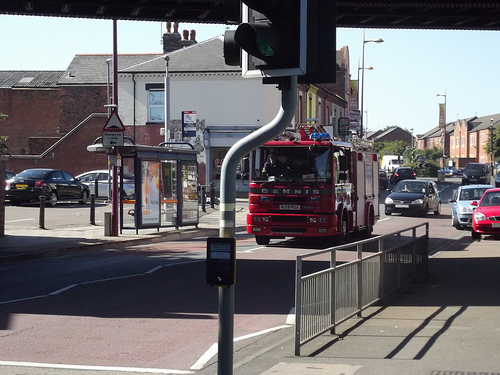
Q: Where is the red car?
A: Lower right corner.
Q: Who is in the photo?
A: No one.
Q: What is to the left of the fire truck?
A: Bus stop.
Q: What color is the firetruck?
A: Red.